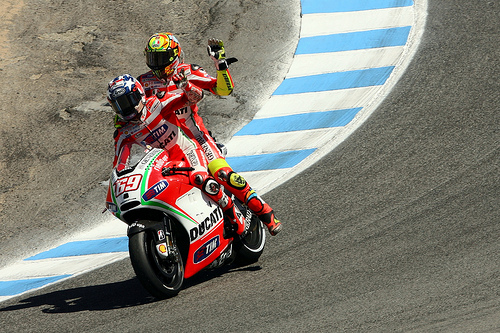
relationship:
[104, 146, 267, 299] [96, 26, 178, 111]
bike are wearing helmets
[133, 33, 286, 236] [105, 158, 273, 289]
men are riding on motorcycle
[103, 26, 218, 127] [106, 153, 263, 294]
men are riding on motorcycle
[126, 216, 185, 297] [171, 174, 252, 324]
front wheel of a motorcycle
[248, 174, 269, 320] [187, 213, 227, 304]
back wheel of a motorcycle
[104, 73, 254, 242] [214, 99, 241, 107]
driver holding a hand up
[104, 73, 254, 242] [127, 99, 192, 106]
driver wearing a red and yellow helmet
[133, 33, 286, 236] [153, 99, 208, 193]
men wearing red and white suits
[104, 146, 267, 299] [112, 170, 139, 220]
bike number 69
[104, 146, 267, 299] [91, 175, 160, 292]
bike leaning to left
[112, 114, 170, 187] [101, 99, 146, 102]
driver wearing a helmet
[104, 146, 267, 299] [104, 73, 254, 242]
bike under two driver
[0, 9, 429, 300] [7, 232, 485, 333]
stripes blue and white on road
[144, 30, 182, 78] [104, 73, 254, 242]
helmet helmets on driver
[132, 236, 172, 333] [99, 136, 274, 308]
front wheel on motorcycle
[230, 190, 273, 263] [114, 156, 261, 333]
back wheel on motorcycle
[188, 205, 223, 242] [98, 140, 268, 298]
lettering printed on motorbike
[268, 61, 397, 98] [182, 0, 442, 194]
line in a curve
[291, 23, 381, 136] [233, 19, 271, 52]
lines on dirt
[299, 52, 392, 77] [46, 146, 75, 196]
lines on dirt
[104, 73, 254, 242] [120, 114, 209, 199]
driver in suit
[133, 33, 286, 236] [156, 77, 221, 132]
men in suit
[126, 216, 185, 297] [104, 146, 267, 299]
front wheel of bike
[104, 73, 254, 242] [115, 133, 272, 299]
driver on motorcycle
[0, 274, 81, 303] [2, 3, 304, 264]
line on dirt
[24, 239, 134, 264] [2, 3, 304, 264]
line on dirt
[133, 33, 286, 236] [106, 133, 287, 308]
men riding a bike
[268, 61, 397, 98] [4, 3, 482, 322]
line on dirt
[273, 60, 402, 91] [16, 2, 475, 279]
line on dirt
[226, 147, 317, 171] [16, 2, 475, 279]
line on dirt